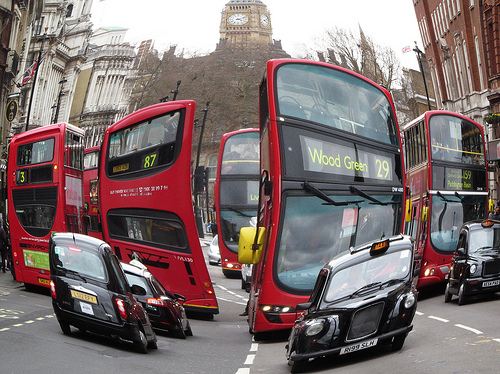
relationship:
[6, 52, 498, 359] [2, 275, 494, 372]
buses on street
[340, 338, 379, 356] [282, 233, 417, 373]
license on car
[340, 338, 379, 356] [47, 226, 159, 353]
license on car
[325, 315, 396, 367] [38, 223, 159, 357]
license on car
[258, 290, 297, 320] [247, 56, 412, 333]
headlight on bus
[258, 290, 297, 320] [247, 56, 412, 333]
headlight turned on bus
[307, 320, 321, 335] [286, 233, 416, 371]
light on vehicle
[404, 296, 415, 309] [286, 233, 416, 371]
light on vehicle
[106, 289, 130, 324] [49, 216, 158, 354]
light on car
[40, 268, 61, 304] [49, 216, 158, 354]
light on car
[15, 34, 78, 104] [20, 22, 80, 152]
flag hanging off building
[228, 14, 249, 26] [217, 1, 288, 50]
clock on building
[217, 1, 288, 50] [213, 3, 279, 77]
building of building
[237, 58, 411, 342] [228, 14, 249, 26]
bus in front of clock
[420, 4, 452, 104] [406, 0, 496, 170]
trim on building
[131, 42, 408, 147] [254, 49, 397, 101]
tree over roof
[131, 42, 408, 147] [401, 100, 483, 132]
tree over roof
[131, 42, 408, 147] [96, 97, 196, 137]
tree over roof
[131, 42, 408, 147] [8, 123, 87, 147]
tree over roof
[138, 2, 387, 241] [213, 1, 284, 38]
building with panels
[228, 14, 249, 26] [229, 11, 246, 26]
clock with numbers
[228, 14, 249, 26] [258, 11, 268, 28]
clock with hands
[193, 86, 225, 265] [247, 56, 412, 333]
pole in front of bus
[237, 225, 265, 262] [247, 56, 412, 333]
mirror in front of bus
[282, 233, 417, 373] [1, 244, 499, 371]
car on road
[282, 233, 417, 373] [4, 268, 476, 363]
car on road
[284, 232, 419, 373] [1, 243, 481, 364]
car in street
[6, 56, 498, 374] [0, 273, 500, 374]
buses on road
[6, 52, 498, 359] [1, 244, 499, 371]
buses on road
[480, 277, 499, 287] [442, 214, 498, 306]
license on car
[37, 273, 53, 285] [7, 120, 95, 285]
license on bus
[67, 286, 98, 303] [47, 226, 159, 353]
license on car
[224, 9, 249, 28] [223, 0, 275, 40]
clock on tower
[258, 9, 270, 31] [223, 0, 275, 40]
clock on tower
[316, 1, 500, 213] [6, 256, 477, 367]
building on side of road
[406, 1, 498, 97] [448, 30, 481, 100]
building on windows